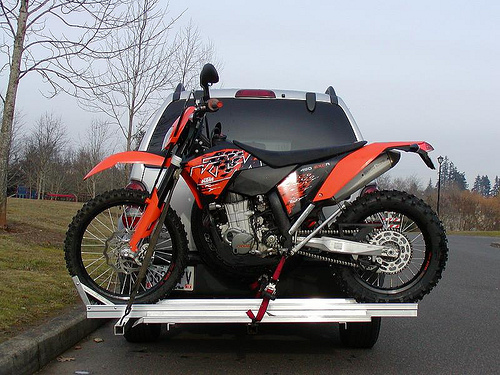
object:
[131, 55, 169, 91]
branch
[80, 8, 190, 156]
tree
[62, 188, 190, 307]
wheel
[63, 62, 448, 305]
motorcycle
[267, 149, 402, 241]
tank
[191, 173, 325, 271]
engine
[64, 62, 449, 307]
bike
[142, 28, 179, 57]
leaves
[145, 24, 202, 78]
no leaves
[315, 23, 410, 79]
day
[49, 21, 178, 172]
view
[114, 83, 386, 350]
suv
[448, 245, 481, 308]
rainswept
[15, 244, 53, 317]
grass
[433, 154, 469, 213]
post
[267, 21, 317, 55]
sky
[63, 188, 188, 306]
tire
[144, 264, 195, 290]
plate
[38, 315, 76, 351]
curb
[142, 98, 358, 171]
window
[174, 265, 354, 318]
bumper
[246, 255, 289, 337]
strap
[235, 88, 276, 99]
light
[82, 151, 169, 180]
fender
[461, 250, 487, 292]
asphalt